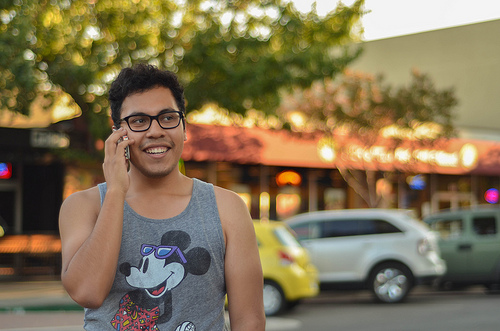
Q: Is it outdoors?
A: Yes, it is outdoors.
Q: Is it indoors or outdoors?
A: It is outdoors.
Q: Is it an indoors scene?
A: No, it is outdoors.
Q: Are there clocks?
A: No, there are no clocks.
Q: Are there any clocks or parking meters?
A: No, there are no clocks or parking meters.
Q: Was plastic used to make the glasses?
A: Yes, the glasses are made of plastic.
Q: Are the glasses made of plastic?
A: Yes, the glasses are made of plastic.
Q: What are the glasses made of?
A: The glasses are made of plastic.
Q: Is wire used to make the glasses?
A: No, the glasses are made of plastic.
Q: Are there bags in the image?
A: No, there are no bags.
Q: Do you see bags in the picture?
A: No, there are no bags.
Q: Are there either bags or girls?
A: No, there are no bags or girls.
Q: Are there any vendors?
A: No, there are no vendors.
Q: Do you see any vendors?
A: No, there are no vendors.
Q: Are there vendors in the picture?
A: No, there are no vendors.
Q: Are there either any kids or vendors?
A: No, there are no vendors or kids.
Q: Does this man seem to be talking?
A: Yes, the man is talking.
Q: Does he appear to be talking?
A: Yes, the man is talking.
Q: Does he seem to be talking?
A: Yes, the man is talking.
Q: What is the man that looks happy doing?
A: The man is talking.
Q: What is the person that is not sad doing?
A: The man is talking.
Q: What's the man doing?
A: The man is talking.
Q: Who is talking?
A: The man is talking.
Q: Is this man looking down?
A: No, the man is talking.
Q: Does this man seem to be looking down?
A: No, the man is talking.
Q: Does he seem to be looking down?
A: No, the man is talking.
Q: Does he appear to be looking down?
A: No, the man is talking.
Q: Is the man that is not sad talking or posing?
A: The man is talking.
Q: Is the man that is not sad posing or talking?
A: The man is talking.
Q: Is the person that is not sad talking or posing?
A: The man is talking.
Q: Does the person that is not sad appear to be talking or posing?
A: The man is talking.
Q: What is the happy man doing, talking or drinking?
A: The man is talking.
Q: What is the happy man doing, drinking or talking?
A: The man is talking.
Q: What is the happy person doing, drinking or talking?
A: The man is talking.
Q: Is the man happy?
A: Yes, the man is happy.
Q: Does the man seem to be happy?
A: Yes, the man is happy.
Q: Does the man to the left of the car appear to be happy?
A: Yes, the man is happy.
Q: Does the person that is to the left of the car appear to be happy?
A: Yes, the man is happy.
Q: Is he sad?
A: No, the man is happy.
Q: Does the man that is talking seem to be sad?
A: No, the man is happy.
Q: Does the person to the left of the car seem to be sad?
A: No, the man is happy.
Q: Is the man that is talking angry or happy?
A: The man is happy.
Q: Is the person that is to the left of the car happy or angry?
A: The man is happy.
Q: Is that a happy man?
A: Yes, that is a happy man.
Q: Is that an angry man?
A: No, that is a happy man.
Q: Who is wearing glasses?
A: The man is wearing glasses.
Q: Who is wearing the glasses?
A: The man is wearing glasses.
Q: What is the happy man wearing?
A: The man is wearing glasses.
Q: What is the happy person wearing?
A: The man is wearing glasses.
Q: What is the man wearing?
A: The man is wearing glasses.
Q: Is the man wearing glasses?
A: Yes, the man is wearing glasses.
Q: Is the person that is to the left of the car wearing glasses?
A: Yes, the man is wearing glasses.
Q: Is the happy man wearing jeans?
A: No, the man is wearing glasses.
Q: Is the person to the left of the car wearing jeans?
A: No, the man is wearing glasses.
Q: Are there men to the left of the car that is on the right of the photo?
A: Yes, there is a man to the left of the car.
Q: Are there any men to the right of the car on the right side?
A: No, the man is to the left of the car.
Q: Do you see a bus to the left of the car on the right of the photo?
A: No, there is a man to the left of the car.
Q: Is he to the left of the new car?
A: Yes, the man is to the left of the car.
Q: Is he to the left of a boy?
A: No, the man is to the left of the car.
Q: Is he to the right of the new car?
A: No, the man is to the left of the car.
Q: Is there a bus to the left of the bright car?
A: No, there is a man to the left of the car.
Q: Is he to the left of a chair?
A: No, the man is to the left of the car.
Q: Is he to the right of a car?
A: No, the man is to the left of a car.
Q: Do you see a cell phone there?
A: Yes, there is a cell phone.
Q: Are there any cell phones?
A: Yes, there is a cell phone.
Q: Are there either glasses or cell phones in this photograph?
A: Yes, there is a cell phone.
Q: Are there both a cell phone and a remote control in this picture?
A: No, there is a cell phone but no remote controls.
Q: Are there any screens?
A: No, there are no screens.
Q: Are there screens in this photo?
A: No, there are no screens.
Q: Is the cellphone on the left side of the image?
A: Yes, the cellphone is on the left of the image.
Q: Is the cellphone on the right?
A: No, the cellphone is on the left of the image.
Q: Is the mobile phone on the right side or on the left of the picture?
A: The mobile phone is on the left of the image.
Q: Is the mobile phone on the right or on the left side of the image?
A: The mobile phone is on the left of the image.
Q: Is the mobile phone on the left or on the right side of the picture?
A: The mobile phone is on the left of the image.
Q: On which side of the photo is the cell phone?
A: The cell phone is on the left of the image.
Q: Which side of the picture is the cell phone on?
A: The cell phone is on the left of the image.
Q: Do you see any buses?
A: No, there are no buses.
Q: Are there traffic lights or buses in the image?
A: No, there are no buses or traffic lights.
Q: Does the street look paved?
A: Yes, the street is paved.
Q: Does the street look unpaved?
A: No, the street is paved.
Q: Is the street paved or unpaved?
A: The street is paved.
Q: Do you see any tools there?
A: No, there are no tools.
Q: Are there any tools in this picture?
A: No, there are no tools.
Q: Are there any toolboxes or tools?
A: No, there are no tools or toolboxes.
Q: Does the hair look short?
A: Yes, the hair is short.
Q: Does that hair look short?
A: Yes, the hair is short.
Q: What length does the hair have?
A: The hair has short length.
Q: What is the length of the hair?
A: The hair is short.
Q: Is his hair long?
A: No, the hair is short.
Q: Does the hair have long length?
A: No, the hair is short.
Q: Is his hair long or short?
A: The hair is short.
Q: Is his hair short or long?
A: The hair is short.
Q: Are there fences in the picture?
A: No, there are no fences.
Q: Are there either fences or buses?
A: No, there are no fences or buses.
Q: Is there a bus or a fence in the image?
A: No, there are no fences or buses.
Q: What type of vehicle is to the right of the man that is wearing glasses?
A: The vehicle is a car.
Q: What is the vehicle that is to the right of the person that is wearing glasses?
A: The vehicle is a car.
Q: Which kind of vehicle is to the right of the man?
A: The vehicle is a car.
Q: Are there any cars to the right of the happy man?
A: Yes, there is a car to the right of the man.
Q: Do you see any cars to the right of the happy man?
A: Yes, there is a car to the right of the man.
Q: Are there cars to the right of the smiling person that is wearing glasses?
A: Yes, there is a car to the right of the man.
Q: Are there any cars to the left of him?
A: No, the car is to the right of the man.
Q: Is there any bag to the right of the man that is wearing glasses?
A: No, there is a car to the right of the man.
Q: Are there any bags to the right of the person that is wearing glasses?
A: No, there is a car to the right of the man.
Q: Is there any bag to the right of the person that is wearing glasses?
A: No, there is a car to the right of the man.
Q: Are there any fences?
A: No, there are no fences.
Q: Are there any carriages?
A: No, there are no carriages.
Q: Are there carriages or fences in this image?
A: No, there are no carriages or fences.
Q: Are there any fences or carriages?
A: No, there are no carriages or fences.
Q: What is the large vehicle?
A: The vehicle is a car.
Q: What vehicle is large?
A: The vehicle is a car.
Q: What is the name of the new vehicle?
A: The vehicle is a car.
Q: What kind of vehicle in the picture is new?
A: The vehicle is a car.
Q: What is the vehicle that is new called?
A: The vehicle is a car.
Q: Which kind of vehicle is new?
A: The vehicle is a car.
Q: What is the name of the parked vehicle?
A: The vehicle is a car.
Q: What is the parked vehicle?
A: The vehicle is a car.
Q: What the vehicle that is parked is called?
A: The vehicle is a car.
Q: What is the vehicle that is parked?
A: The vehicle is a car.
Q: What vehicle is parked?
A: The vehicle is a car.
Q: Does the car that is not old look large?
A: Yes, the car is large.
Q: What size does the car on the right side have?
A: The car has large size.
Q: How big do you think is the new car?
A: The car is large.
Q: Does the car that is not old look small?
A: No, the car is large.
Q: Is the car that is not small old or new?
A: The car is new.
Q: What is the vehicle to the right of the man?
A: The vehicle is a car.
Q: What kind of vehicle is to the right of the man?
A: The vehicle is a car.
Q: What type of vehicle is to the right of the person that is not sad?
A: The vehicle is a car.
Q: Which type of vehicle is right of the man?
A: The vehicle is a car.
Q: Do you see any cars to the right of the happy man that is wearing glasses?
A: Yes, there is a car to the right of the man.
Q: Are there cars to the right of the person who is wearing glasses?
A: Yes, there is a car to the right of the man.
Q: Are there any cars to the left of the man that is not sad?
A: No, the car is to the right of the man.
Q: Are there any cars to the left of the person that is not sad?
A: No, the car is to the right of the man.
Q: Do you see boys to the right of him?
A: No, there is a car to the right of the man.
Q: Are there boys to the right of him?
A: No, there is a car to the right of the man.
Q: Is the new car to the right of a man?
A: Yes, the car is to the right of a man.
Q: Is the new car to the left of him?
A: No, the car is to the right of the man.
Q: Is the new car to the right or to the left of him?
A: The car is to the right of the man.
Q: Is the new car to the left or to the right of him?
A: The car is to the right of the man.